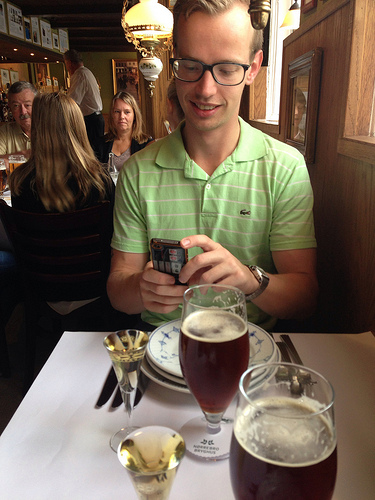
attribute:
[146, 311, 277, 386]
plate — circular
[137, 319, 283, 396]
plate — circular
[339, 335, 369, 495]
table cloth — white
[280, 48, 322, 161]
picture — framed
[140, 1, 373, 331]
wall — brown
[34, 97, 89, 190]
hair — blonde, woman's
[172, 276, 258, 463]
glass — full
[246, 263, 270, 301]
watch — silver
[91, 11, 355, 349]
person — white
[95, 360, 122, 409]
knife — silver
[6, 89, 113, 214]
hair — long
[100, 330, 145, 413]
cup — gold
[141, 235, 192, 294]
phone — cellular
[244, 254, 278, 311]
wrist — person's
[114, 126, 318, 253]
shirt — green